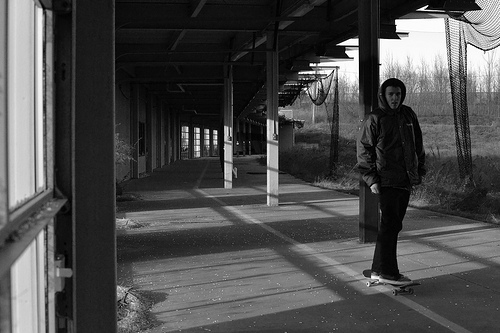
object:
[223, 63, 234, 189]
beam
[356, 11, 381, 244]
beam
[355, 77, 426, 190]
jacket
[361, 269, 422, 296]
skateboard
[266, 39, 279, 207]
post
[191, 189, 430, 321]
line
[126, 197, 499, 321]
sidewalk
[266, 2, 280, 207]
beam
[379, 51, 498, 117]
tree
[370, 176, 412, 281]
pants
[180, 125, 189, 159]
window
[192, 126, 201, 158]
window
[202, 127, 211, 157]
window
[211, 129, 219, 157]
window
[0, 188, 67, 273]
window sill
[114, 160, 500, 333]
concrete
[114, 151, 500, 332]
platform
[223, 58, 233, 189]
wooden post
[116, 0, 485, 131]
roof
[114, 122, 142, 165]
bush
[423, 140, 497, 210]
weeds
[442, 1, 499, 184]
net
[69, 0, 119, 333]
beam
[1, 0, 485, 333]
building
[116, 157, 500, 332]
ground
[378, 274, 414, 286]
shoe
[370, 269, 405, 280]
shoe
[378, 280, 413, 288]
sole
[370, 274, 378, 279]
sole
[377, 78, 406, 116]
hood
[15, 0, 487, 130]
platform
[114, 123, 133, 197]
no leaves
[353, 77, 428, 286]
guy